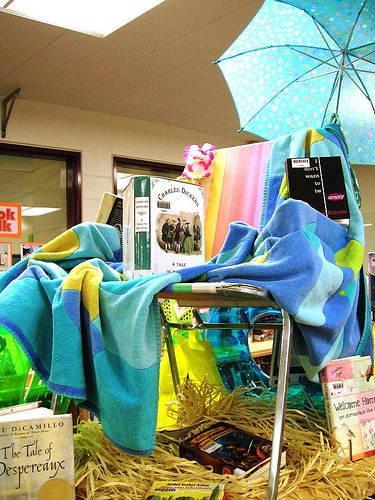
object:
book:
[145, 481, 226, 500]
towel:
[0, 123, 374, 454]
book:
[284, 156, 351, 226]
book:
[320, 354, 374, 464]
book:
[122, 175, 205, 281]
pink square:
[318, 358, 354, 383]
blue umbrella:
[212, 1, 375, 166]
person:
[161, 214, 201, 253]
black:
[293, 162, 323, 201]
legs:
[160, 304, 294, 497]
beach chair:
[156, 281, 294, 498]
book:
[178, 420, 287, 480]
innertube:
[205, 307, 326, 418]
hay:
[72, 371, 375, 499]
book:
[0, 401, 75, 498]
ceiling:
[1, 0, 267, 137]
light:
[0, 0, 166, 35]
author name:
[11, 421, 64, 432]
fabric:
[157, 281, 269, 294]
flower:
[181, 142, 216, 180]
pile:
[148, 409, 297, 496]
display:
[5, 110, 374, 497]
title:
[0, 441, 65, 498]